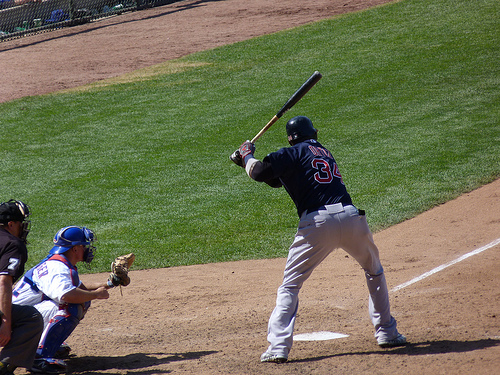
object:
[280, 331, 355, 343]
home plate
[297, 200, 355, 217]
belt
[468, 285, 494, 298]
dirt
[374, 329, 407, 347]
shoes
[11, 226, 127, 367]
man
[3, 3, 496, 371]
baseball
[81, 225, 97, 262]
mask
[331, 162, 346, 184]
number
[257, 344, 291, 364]
shoes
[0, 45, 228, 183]
ground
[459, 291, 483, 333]
clay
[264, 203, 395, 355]
pants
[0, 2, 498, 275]
grass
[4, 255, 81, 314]
shirt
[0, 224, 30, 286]
shirt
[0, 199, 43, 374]
umpire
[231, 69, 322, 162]
bat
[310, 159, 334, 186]
number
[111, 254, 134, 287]
glove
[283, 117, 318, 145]
helmet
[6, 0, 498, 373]
field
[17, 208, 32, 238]
face mask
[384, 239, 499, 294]
line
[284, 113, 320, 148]
head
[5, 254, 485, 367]
mound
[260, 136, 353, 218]
jersey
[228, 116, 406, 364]
player